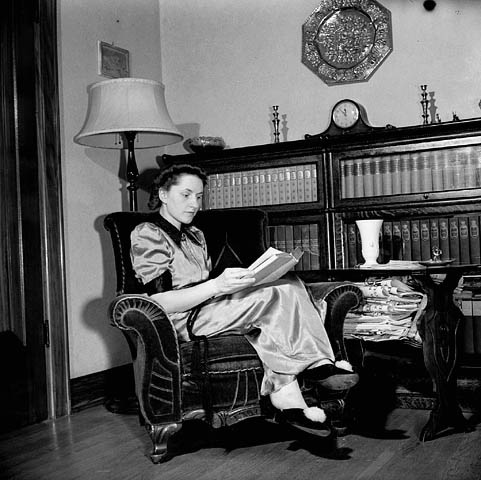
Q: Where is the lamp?
A: Behind the chair.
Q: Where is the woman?
A: In the chair.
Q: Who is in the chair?
A: The woman.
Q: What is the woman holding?
A: A book.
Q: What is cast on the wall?
A: Shadows.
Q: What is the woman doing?
A: Reading.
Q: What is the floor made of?
A: Wood.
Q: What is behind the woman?
A: A lamp.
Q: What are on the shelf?
A: Books.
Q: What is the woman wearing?
A: A dress.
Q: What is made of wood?
A: The floor.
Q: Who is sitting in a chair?
A: The woman.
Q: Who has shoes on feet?
A: The woman.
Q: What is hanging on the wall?
A: A plate.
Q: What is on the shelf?
A: Books.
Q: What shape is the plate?
A: Octagon.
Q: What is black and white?
A: The picture.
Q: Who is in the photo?
A: A lady.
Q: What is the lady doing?
A: Reading.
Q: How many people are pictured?
A: One.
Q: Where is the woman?
A: In the chair.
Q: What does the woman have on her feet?
A: Slippers.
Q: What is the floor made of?
A: Wood.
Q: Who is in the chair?
A: The woman.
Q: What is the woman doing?
A: Reading.